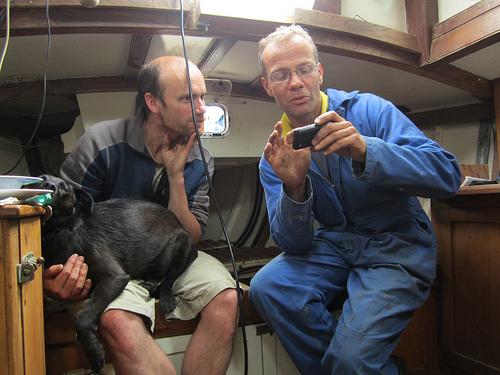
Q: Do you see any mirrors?
A: No, there are no mirrors.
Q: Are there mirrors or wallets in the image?
A: No, there are no mirrors or wallets.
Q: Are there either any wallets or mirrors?
A: No, there are no mirrors or wallets.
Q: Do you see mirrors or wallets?
A: No, there are no mirrors or wallets.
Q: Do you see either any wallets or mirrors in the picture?
A: No, there are no mirrors or wallets.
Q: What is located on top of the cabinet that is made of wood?
A: The dishes are on top of the cabinet.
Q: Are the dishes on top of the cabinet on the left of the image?
A: Yes, the dishes are on top of the cabinet.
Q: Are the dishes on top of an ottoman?
A: No, the dishes are on top of the cabinet.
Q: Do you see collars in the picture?
A: Yes, there is a collar.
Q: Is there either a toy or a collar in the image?
A: Yes, there is a collar.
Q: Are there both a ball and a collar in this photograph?
A: No, there is a collar but no balls.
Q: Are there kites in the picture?
A: No, there are no kites.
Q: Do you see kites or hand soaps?
A: No, there are no kites or hand soaps.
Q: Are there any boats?
A: Yes, there is a boat.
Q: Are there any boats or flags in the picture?
A: Yes, there is a boat.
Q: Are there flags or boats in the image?
A: Yes, there is a boat.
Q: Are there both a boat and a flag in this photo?
A: No, there is a boat but no flags.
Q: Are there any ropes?
A: No, there are no ropes.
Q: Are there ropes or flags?
A: No, there are no ropes or flags.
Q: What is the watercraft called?
A: The watercraft is a boat.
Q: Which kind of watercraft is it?
A: The watercraft is a boat.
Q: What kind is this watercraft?
A: This is a boat.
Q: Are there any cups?
A: Yes, there is a cup.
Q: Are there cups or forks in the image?
A: Yes, there is a cup.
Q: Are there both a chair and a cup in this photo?
A: No, there is a cup but no chairs.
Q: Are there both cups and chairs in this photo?
A: No, there is a cup but no chairs.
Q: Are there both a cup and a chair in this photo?
A: No, there is a cup but no chairs.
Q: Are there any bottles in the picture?
A: No, there are no bottles.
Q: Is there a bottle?
A: No, there are no bottles.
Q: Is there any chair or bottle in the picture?
A: No, there are no bottles or chairs.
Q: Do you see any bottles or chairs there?
A: No, there are no bottles or chairs.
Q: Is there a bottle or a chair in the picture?
A: No, there are no bottles or chairs.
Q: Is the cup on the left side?
A: Yes, the cup is on the left of the image.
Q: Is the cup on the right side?
A: No, the cup is on the left of the image.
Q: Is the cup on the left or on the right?
A: The cup is on the left of the image.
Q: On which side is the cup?
A: The cup is on the left of the image.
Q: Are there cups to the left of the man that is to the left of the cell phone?
A: Yes, there is a cup to the left of the man.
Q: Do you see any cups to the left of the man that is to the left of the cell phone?
A: Yes, there is a cup to the left of the man.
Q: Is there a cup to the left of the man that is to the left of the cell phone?
A: Yes, there is a cup to the left of the man.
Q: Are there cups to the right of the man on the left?
A: No, the cup is to the left of the man.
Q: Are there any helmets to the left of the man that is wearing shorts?
A: No, there is a cup to the left of the man.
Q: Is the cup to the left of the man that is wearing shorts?
A: Yes, the cup is to the left of the man.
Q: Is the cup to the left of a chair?
A: No, the cup is to the left of the man.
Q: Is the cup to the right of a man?
A: No, the cup is to the left of a man.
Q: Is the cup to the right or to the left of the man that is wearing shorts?
A: The cup is to the left of the man.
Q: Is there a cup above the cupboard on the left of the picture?
A: Yes, there is a cup above the cupboard.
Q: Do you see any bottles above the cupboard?
A: No, there is a cup above the cupboard.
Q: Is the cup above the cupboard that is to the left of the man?
A: Yes, the cup is above the cupboard.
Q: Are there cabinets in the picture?
A: Yes, there is a cabinet.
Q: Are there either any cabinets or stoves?
A: Yes, there is a cabinet.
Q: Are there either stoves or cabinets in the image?
A: Yes, there is a cabinet.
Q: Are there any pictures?
A: No, there are no pictures.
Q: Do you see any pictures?
A: No, there are no pictures.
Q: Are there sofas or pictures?
A: No, there are no pictures or sofas.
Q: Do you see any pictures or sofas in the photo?
A: No, there are no pictures or sofas.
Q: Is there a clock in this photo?
A: No, there are no clocks.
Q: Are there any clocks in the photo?
A: No, there are no clocks.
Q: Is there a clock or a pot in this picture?
A: No, there are no clocks or pots.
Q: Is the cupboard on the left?
A: Yes, the cupboard is on the left of the image.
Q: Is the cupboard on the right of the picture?
A: No, the cupboard is on the left of the image.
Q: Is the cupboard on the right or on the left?
A: The cupboard is on the left of the image.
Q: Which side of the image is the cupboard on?
A: The cupboard is on the left of the image.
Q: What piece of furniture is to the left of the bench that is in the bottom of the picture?
A: The piece of furniture is a cupboard.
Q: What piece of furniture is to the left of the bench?
A: The piece of furniture is a cupboard.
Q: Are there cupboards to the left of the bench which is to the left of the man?
A: Yes, there is a cupboard to the left of the bench.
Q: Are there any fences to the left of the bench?
A: No, there is a cupboard to the left of the bench.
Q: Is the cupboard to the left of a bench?
A: Yes, the cupboard is to the left of a bench.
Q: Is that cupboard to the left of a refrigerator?
A: No, the cupboard is to the left of a bench.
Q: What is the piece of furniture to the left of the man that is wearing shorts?
A: The piece of furniture is a cupboard.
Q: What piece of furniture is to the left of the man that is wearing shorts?
A: The piece of furniture is a cupboard.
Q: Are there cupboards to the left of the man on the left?
A: Yes, there is a cupboard to the left of the man.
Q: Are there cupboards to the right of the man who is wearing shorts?
A: No, the cupboard is to the left of the man.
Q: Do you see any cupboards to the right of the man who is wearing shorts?
A: No, the cupboard is to the left of the man.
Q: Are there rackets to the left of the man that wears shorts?
A: No, there is a cupboard to the left of the man.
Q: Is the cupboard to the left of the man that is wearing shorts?
A: Yes, the cupboard is to the left of the man.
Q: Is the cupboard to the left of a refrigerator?
A: No, the cupboard is to the left of the man.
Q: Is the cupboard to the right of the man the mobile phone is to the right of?
A: No, the cupboard is to the left of the man.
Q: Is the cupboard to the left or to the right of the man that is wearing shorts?
A: The cupboard is to the left of the man.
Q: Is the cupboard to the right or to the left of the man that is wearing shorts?
A: The cupboard is to the left of the man.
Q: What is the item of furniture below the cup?
A: The piece of furniture is a cupboard.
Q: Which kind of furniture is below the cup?
A: The piece of furniture is a cupboard.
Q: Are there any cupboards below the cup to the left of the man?
A: Yes, there is a cupboard below the cup.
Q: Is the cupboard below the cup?
A: Yes, the cupboard is below the cup.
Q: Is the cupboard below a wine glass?
A: No, the cupboard is below the cup.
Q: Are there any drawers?
A: No, there are no drawers.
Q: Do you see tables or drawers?
A: No, there are no drawers or tables.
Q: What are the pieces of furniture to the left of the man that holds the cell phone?
A: The pieces of furniture are cabinets.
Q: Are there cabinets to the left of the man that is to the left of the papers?
A: Yes, there are cabinets to the left of the man.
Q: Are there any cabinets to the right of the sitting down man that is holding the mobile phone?
A: No, the cabinets are to the left of the man.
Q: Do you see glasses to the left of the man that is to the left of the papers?
A: No, there are cabinets to the left of the man.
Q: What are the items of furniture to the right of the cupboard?
A: The pieces of furniture are cabinets.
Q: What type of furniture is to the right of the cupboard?
A: The pieces of furniture are cabinets.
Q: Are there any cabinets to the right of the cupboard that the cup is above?
A: Yes, there are cabinets to the right of the cupboard.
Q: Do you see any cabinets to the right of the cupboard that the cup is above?
A: Yes, there are cabinets to the right of the cupboard.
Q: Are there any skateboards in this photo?
A: No, there are no skateboards.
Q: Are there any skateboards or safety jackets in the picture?
A: No, there are no skateboards or safety jackets.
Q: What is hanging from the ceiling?
A: The wires are hanging from the ceiling.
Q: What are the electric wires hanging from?
A: The wires are hanging from the ceiling.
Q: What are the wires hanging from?
A: The wires are hanging from the ceiling.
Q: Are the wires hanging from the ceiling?
A: Yes, the wires are hanging from the ceiling.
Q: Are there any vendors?
A: No, there are no vendors.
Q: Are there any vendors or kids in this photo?
A: No, there are no vendors or kids.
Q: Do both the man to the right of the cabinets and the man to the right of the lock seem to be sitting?
A: Yes, both the man and the man are sitting.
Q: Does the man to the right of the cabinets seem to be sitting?
A: Yes, the man is sitting.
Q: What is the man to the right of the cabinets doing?
A: The man is sitting.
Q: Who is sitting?
A: The man is sitting.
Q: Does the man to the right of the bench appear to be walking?
A: No, the man is sitting.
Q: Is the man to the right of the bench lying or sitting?
A: The man is sitting.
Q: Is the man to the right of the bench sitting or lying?
A: The man is sitting.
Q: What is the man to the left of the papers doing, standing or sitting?
A: The man is sitting.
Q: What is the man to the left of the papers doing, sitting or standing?
A: The man is sitting.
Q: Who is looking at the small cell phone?
A: The man is looking at the cell phone.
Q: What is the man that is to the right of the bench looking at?
A: The man is looking at the cellphone.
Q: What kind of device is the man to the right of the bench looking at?
A: The man is looking at the cellphone.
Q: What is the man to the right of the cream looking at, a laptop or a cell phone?
A: The man is looking at a cell phone.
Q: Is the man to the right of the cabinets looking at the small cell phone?
A: Yes, the man is looking at the cellphone.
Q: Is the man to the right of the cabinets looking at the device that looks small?
A: Yes, the man is looking at the cellphone.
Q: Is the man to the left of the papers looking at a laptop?
A: No, the man is looking at the cellphone.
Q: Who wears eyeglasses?
A: The man wears eyeglasses.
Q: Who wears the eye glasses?
A: The man wears eyeglasses.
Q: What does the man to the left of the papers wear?
A: The man wears eye glasses.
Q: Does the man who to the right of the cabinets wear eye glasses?
A: Yes, the man wears eye glasses.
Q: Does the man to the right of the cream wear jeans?
A: No, the man wears eye glasses.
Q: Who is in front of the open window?
A: The man is in front of the window.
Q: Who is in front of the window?
A: The man is in front of the window.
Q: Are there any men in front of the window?
A: Yes, there is a man in front of the window.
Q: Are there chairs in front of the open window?
A: No, there is a man in front of the window.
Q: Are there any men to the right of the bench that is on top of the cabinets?
A: Yes, there is a man to the right of the bench.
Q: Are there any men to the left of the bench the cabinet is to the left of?
A: No, the man is to the right of the bench.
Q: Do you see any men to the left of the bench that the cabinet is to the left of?
A: No, the man is to the right of the bench.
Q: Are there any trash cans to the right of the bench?
A: No, there is a man to the right of the bench.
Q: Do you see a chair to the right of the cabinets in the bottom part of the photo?
A: No, there is a man to the right of the cabinets.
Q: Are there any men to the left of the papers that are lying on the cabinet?
A: Yes, there is a man to the left of the papers.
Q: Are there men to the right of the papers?
A: No, the man is to the left of the papers.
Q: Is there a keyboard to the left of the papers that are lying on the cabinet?
A: No, there is a man to the left of the papers.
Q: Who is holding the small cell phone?
A: The man is holding the mobile phone.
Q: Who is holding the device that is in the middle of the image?
A: The man is holding the mobile phone.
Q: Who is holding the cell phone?
A: The man is holding the mobile phone.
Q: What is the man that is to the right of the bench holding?
A: The man is holding the cellphone.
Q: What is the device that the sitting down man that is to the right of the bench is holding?
A: The device is a cell phone.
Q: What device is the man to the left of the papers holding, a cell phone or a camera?
A: The man is holding a cell phone.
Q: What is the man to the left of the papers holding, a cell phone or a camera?
A: The man is holding a cell phone.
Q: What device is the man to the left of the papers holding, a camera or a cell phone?
A: The man is holding a cell phone.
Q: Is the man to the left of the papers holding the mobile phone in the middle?
A: Yes, the man is holding the mobile phone.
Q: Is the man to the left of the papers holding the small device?
A: Yes, the man is holding the mobile phone.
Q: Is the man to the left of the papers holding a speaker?
A: No, the man is holding the mobile phone.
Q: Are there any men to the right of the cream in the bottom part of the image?
A: Yes, there is a man to the right of the cream.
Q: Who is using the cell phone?
A: The man is using the cell phone.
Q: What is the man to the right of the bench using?
A: The man is using a mobile phone.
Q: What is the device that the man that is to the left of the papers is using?
A: The device is a cell phone.